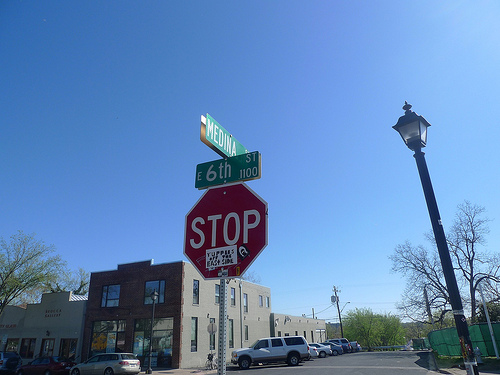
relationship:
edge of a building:
[171, 260, 190, 370] [78, 259, 279, 372]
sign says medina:
[196, 110, 244, 158] [207, 118, 237, 153]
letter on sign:
[217, 160, 227, 181] [190, 148, 263, 191]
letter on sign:
[245, 153, 253, 166] [190, 148, 263, 191]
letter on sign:
[249, 149, 259, 163] [190, 148, 263, 191]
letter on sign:
[196, 168, 204, 183] [190, 148, 263, 191]